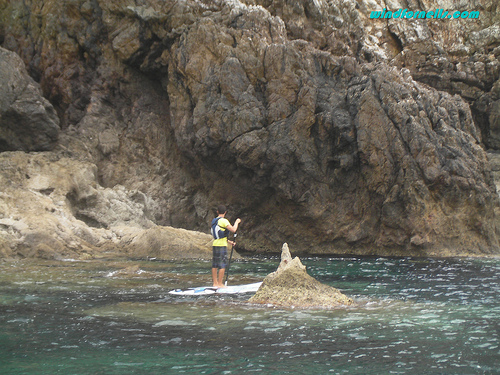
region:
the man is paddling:
[173, 185, 274, 307]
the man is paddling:
[122, 150, 276, 316]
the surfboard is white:
[166, 266, 305, 306]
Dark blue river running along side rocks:
[7, 268, 217, 372]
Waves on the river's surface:
[143, 309, 318, 374]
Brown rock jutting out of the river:
[267, 253, 329, 318]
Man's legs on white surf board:
[211, 272, 236, 292]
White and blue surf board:
[175, 283, 260, 296]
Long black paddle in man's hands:
[227, 224, 233, 284]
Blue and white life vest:
[208, 218, 228, 245]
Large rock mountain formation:
[107, 46, 409, 243]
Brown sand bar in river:
[121, 302, 284, 335]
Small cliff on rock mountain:
[3, 50, 65, 138]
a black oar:
[223, 228, 238, 285]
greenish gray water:
[5, 256, 497, 372]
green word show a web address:
[368, 5, 480, 20]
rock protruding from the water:
[247, 241, 351, 311]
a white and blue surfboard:
[167, 281, 261, 296]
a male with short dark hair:
[208, 203, 240, 288]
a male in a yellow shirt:
[208, 205, 241, 288]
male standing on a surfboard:
[166, 202, 262, 295]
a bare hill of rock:
[1, 1, 498, 257]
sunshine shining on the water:
[85, 299, 497, 339]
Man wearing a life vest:
[167, 203, 278, 296]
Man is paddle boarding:
[167, 204, 282, 295]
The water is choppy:
[6, 255, 169, 372]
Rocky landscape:
[166, 3, 498, 193]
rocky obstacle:
[245, 239, 364, 313]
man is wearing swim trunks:
[207, 240, 229, 273]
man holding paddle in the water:
[205, 203, 241, 284]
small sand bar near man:
[100, 295, 445, 327]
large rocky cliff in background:
[158, 0, 483, 215]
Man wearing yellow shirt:
[207, 203, 239, 252]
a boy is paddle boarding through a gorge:
[4, 3, 492, 366]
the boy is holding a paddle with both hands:
[208, 206, 245, 291]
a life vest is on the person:
[207, 216, 227, 243]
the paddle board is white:
[163, 278, 270, 304]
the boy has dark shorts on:
[210, 242, 230, 273]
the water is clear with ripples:
[61, 257, 486, 362]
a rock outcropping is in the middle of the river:
[244, 240, 361, 328]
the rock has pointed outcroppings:
[251, 235, 336, 312]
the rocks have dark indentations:
[11, 5, 498, 284]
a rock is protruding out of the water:
[96, 255, 158, 292]